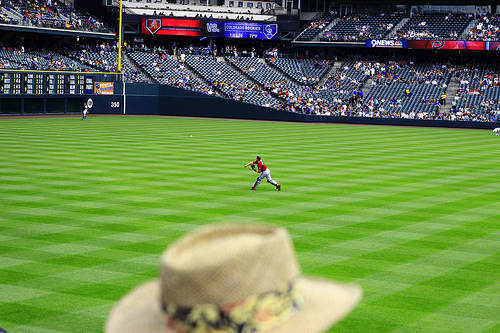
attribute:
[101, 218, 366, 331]
hat — brimmed, brown, blurry, straw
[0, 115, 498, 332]
field — checkered, grass, green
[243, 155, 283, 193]
catcher — throwing, running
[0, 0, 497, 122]
stand — empty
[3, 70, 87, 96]
scoreboard — digital, lectronic, electronic, statistical, large, blue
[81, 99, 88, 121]
outfielder — throwing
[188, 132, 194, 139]
ball — airborne, flying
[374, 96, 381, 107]
spectator — watching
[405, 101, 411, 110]
seat — empty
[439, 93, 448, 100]
shirt — yellow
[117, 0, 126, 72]
pole — foul, yellow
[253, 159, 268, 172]
jersey — red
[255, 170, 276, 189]
pants — gray